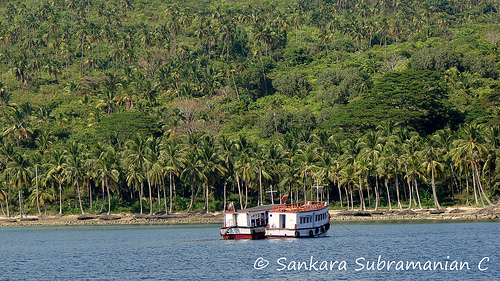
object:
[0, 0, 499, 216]
hill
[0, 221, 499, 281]
water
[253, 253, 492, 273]
print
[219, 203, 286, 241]
boat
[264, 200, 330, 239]
boat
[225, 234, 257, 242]
trim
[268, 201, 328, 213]
railings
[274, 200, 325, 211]
top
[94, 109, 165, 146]
trees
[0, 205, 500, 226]
shore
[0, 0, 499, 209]
jungle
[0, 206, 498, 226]
beach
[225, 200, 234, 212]
flags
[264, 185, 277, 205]
cross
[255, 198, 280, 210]
front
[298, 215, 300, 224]
windows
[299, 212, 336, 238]
side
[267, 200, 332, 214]
roof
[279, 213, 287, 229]
door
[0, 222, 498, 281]
ripple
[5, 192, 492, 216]
trunks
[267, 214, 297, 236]
back